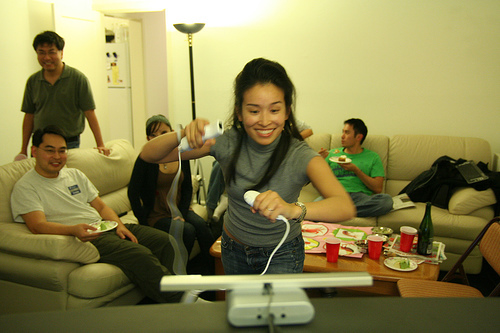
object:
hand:
[71, 223, 101, 242]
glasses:
[37, 147, 67, 154]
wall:
[0, 0, 500, 166]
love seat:
[0, 140, 228, 314]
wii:
[160, 271, 372, 292]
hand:
[186, 118, 211, 149]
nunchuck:
[244, 190, 284, 219]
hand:
[250, 190, 288, 223]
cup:
[323, 240, 341, 262]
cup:
[367, 237, 382, 260]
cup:
[400, 226, 418, 252]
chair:
[397, 219, 500, 297]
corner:
[418, 267, 438, 280]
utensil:
[384, 257, 419, 271]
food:
[399, 261, 409, 268]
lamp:
[171, 6, 204, 118]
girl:
[140, 57, 356, 274]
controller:
[244, 190, 285, 219]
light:
[173, 22, 204, 120]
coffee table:
[211, 221, 440, 296]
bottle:
[417, 202, 434, 255]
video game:
[159, 271, 372, 291]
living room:
[0, 0, 499, 333]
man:
[13, 31, 110, 162]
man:
[316, 118, 393, 216]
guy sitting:
[10, 125, 193, 309]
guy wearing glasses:
[8, 127, 209, 304]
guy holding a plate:
[327, 148, 360, 172]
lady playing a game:
[136, 55, 357, 325]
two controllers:
[178, 121, 285, 222]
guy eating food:
[309, 119, 403, 219]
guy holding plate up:
[309, 111, 415, 221]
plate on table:
[383, 256, 417, 272]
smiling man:
[28, 135, 83, 177]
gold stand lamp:
[172, 8, 207, 121]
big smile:
[245, 118, 282, 141]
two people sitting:
[14, 107, 215, 302]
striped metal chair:
[440, 218, 500, 298]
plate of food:
[338, 155, 346, 161]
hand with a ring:
[249, 189, 329, 235]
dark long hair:
[226, 57, 304, 192]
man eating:
[306, 105, 396, 218]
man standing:
[15, 26, 124, 171]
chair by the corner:
[483, 218, 500, 230]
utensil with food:
[384, 257, 418, 271]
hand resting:
[6, 194, 108, 250]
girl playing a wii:
[139, 59, 367, 304]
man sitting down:
[297, 102, 413, 220]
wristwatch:
[294, 201, 306, 222]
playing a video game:
[167, 113, 367, 330]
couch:
[0, 133, 500, 313]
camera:
[226, 284, 314, 326]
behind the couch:
[7, 28, 157, 164]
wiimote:
[139, 56, 355, 275]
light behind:
[160, 12, 215, 47]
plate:
[329, 157, 352, 164]